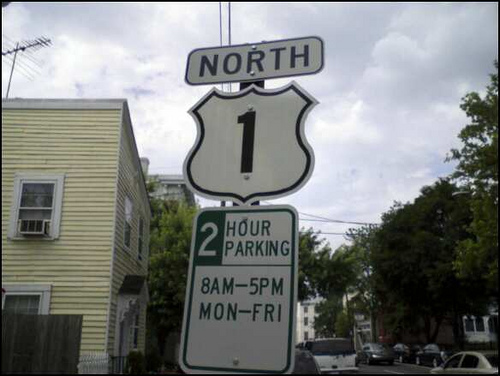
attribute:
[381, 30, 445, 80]
clouds — white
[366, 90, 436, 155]
clouds — white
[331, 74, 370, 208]
clouds — white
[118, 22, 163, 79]
clouds — white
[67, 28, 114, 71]
clouds — white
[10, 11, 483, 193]
sky — blue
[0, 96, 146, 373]
house — white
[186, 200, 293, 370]
sign — parking, white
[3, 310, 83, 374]
fence — wooden, tall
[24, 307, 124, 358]
fence — wooden, brown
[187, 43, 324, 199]
sign — black, white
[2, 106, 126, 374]
siding — yellow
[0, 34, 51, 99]
antenna — television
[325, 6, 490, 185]
sky — blue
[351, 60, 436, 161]
clouds — white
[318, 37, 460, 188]
clouds — white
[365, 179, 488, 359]
tree — green, small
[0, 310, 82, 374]
brown fence — small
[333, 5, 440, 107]
clouds — white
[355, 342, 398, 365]
car — grey, smaLL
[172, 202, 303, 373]
sign — green, white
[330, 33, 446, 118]
clouds — white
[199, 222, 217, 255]
number — white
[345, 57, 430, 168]
clouds — flying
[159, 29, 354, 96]
sign — white, black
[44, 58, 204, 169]
clouds — white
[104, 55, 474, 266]
sky — blue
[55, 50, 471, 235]
sky — blue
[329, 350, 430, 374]
road — busy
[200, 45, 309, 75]
lettering — black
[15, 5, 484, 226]
sky — blue